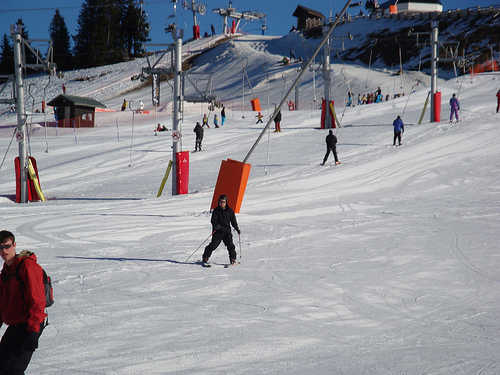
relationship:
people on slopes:
[0, 63, 493, 373] [1, 13, 496, 373]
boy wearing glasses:
[1, 226, 52, 371] [1, 238, 14, 250]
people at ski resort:
[1, 83, 499, 365] [0, 11, 500, 373]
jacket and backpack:
[0, 250, 48, 339] [42, 265, 54, 310]